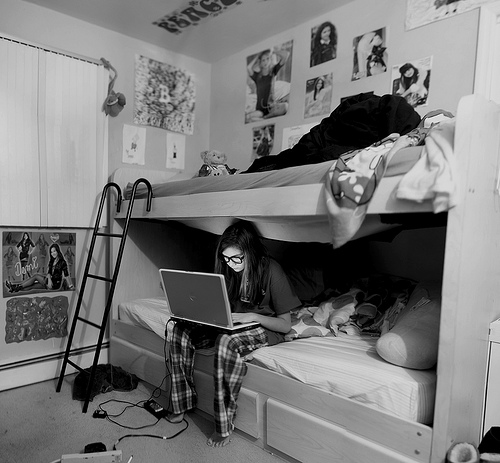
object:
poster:
[151, 0, 245, 36]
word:
[152, 22, 178, 33]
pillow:
[376, 281, 442, 369]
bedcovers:
[118, 296, 437, 425]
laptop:
[158, 268, 261, 335]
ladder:
[55, 178, 153, 413]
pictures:
[2, 231, 78, 298]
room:
[4, 3, 496, 463]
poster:
[133, 54, 197, 136]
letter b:
[158, 84, 170, 104]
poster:
[391, 55, 432, 109]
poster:
[165, 133, 185, 168]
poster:
[310, 21, 337, 67]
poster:
[351, 27, 387, 82]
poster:
[252, 124, 274, 159]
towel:
[73, 364, 139, 402]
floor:
[12, 388, 51, 458]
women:
[17, 233, 35, 281]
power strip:
[60, 449, 123, 461]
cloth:
[241, 93, 423, 175]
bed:
[110, 297, 500, 463]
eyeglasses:
[223, 256, 244, 264]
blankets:
[325, 109, 459, 250]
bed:
[109, 93, 500, 229]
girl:
[167, 221, 293, 448]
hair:
[216, 221, 270, 312]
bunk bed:
[106, 93, 499, 462]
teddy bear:
[199, 150, 240, 177]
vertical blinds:
[0, 38, 107, 228]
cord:
[99, 373, 189, 450]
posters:
[304, 72, 333, 119]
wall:
[204, 2, 446, 73]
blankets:
[285, 278, 417, 342]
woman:
[247, 49, 288, 123]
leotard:
[250, 63, 284, 115]